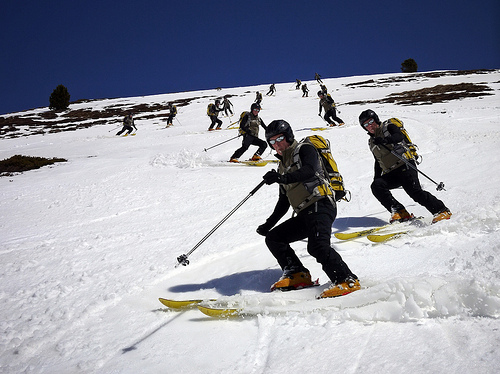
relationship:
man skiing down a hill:
[255, 118, 361, 299] [0, 66, 499, 372]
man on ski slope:
[255, 118, 361, 299] [151, 286, 263, 318]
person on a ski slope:
[228, 97, 272, 166] [0, 70, 499, 371]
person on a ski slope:
[312, 89, 347, 131] [54, 174, 141, 229]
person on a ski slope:
[204, 96, 226, 130] [0, 65, 500, 370]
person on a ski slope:
[161, 96, 178, 133] [0, 70, 499, 371]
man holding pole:
[268, 125, 345, 292] [171, 168, 282, 271]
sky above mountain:
[0, 2, 500, 115] [0, 67, 499, 370]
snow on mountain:
[1, 61, 497, 371] [0, 67, 499, 370]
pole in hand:
[177, 219, 237, 255] [261, 167, 283, 185]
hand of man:
[261, 167, 283, 185] [255, 118, 361, 299]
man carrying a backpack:
[255, 118, 361, 299] [298, 132, 348, 202]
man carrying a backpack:
[359, 109, 451, 224] [381, 117, 417, 163]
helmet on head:
[264, 122, 299, 160] [262, 112, 302, 158]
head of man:
[262, 112, 302, 158] [255, 118, 361, 299]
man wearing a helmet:
[255, 118, 361, 299] [264, 122, 299, 160]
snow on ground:
[239, 304, 411, 369] [352, 231, 467, 313]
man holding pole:
[255, 118, 361, 299] [171, 168, 282, 271]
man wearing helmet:
[255, 118, 361, 299] [263, 117, 291, 134]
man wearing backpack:
[255, 118, 361, 299] [298, 132, 348, 202]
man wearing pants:
[255, 118, 361, 299] [260, 198, 354, 281]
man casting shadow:
[255, 118, 361, 299] [120, 262, 284, 357]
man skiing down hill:
[255, 118, 361, 299] [0, 66, 499, 372]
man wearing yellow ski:
[358, 107, 453, 224] [368, 228, 404, 244]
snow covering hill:
[64, 169, 245, 347] [10, 39, 485, 361]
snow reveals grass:
[39, 197, 76, 248] [9, 159, 18, 172]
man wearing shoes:
[255, 118, 361, 299] [270, 269, 360, 299]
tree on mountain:
[398, 57, 420, 72] [334, 68, 498, 160]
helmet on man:
[264, 119, 295, 151] [255, 118, 361, 299]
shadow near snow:
[152, 246, 314, 326] [1, 61, 497, 371]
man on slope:
[358, 107, 453, 224] [42, 62, 491, 229]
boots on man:
[271, 268, 363, 297] [255, 118, 361, 299]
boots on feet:
[271, 268, 363, 297] [267, 272, 361, 299]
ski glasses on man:
[266, 133, 284, 145] [208, 117, 353, 322]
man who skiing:
[255, 118, 361, 299] [124, 242, 389, 374]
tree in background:
[38, 100, 92, 227] [1, 76, 491, 196]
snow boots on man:
[319, 238, 359, 327] [214, 123, 362, 289]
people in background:
[199, 69, 346, 169] [8, 54, 478, 151]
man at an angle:
[255, 118, 361, 299] [166, 162, 354, 345]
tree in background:
[47, 82, 72, 114] [44, 51, 480, 161]